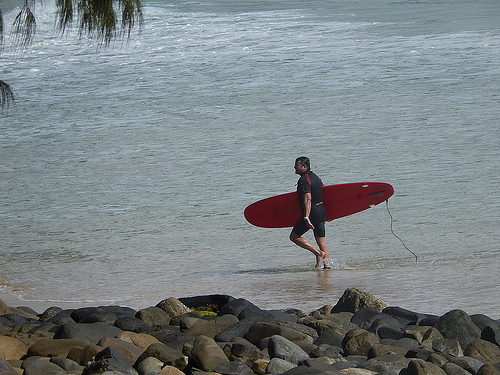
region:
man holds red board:
[233, 190, 386, 233]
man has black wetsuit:
[296, 172, 331, 233]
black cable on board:
[362, 165, 424, 260]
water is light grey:
[50, 57, 190, 172]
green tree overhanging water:
[0, 12, 145, 129]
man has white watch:
[295, 210, 310, 225]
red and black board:
[262, 176, 377, 228]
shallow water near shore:
[185, 239, 340, 327]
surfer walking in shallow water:
[239, 154, 396, 274]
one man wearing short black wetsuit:
[288, 153, 330, 270]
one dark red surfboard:
[238, 177, 395, 231]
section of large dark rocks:
[7, 293, 492, 374]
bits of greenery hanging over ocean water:
[9, 2, 153, 53]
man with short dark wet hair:
[291, 152, 313, 175]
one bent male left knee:
[288, 221, 310, 250]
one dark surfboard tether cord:
[381, 192, 424, 270]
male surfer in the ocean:
[236, 116, 441, 278]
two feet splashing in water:
[303, 244, 346, 274]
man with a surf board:
[242, 155, 395, 267]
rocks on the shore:
[0, 289, 499, 374]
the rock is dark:
[353, 308, 396, 331]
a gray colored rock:
[268, 333, 308, 362]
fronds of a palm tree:
[1, 0, 143, 111]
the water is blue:
[2, 0, 499, 319]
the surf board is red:
[244, 181, 394, 226]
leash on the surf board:
[385, 200, 419, 262]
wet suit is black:
[295, 173, 325, 236]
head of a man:
[294, 157, 309, 172]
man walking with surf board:
[233, 129, 418, 276]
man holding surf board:
[216, 153, 433, 269]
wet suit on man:
[280, 173, 332, 252]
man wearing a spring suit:
[276, 148, 349, 280]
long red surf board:
[239, 174, 399, 229]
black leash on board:
[385, 199, 427, 274]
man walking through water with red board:
[225, 148, 437, 288]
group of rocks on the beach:
[15, 280, 267, 373]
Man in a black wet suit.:
[277, 141, 329, 244]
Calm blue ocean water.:
[46, 113, 173, 223]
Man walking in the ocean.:
[277, 138, 353, 276]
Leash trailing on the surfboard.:
[379, 169, 419, 275]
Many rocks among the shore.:
[149, 287, 406, 364]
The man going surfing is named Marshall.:
[277, 134, 339, 270]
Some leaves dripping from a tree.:
[12, 4, 156, 63]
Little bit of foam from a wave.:
[41, 15, 191, 94]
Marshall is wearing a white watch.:
[297, 210, 319, 223]